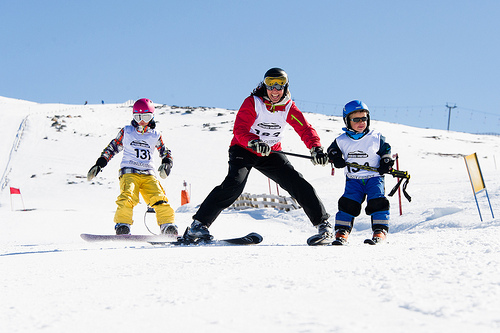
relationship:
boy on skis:
[324, 98, 399, 241] [80, 224, 392, 245]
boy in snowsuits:
[324, 98, 399, 241] [105, 93, 407, 224]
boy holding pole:
[318, 97, 407, 231] [385, 153, 410, 211]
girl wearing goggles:
[89, 95, 191, 233] [132, 106, 159, 125]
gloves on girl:
[81, 163, 174, 175] [89, 95, 191, 233]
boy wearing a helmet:
[318, 97, 407, 231] [340, 97, 367, 130]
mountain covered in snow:
[4, 97, 485, 332] [0, 97, 498, 329]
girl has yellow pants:
[89, 95, 191, 233] [115, 167, 174, 229]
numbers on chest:
[129, 140, 156, 167] [120, 126, 164, 156]